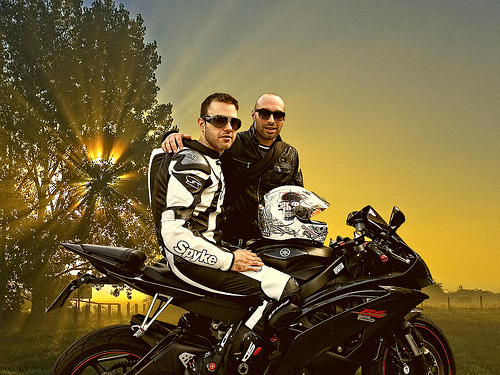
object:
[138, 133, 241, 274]
jacket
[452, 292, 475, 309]
cow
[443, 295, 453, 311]
rod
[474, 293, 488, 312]
rod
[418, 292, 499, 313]
fencing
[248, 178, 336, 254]
helmet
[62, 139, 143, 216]
sun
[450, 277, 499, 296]
trees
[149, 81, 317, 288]
man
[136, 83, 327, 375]
men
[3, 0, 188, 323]
tree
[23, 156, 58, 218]
branches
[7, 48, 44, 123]
branches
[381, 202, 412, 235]
mirror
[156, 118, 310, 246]
jacket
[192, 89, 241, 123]
hair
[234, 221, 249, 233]
black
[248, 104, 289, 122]
sunglasses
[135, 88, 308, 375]
man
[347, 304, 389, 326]
logo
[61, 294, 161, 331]
fence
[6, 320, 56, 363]
pasture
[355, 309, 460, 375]
tire rim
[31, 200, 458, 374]
pasta salad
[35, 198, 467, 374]
black motorcycle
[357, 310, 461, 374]
red trim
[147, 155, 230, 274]
arm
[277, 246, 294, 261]
logo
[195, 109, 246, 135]
sunglasses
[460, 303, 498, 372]
pasture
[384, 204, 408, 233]
light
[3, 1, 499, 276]
sunset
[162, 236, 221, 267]
word spyke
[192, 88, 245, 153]
head